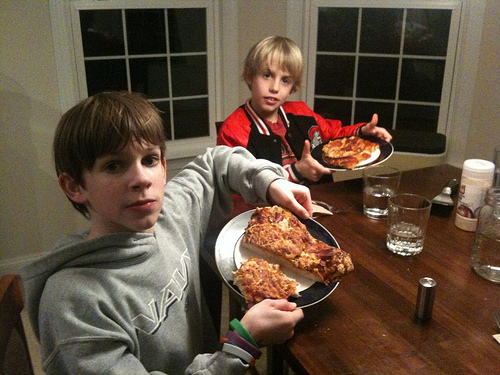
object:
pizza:
[321, 135, 381, 170]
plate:
[310, 135, 394, 171]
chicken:
[232, 257, 303, 304]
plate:
[214, 205, 342, 310]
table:
[199, 164, 496, 375]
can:
[455, 158, 496, 232]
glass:
[385, 193, 432, 257]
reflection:
[214, 220, 249, 271]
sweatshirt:
[19, 144, 289, 375]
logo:
[131, 246, 192, 336]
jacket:
[217, 98, 368, 198]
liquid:
[386, 223, 425, 256]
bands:
[221, 317, 263, 365]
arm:
[43, 278, 255, 375]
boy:
[216, 34, 392, 198]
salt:
[414, 276, 437, 322]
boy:
[18, 91, 313, 375]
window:
[312, 3, 456, 134]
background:
[0, 0, 499, 266]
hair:
[239, 35, 304, 94]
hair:
[52, 92, 167, 220]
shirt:
[260, 114, 299, 167]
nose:
[128, 156, 153, 191]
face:
[82, 131, 165, 230]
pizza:
[231, 205, 355, 304]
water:
[472, 231, 500, 281]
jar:
[469, 188, 500, 282]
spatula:
[430, 178, 460, 218]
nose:
[269, 74, 281, 94]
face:
[251, 55, 295, 112]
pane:
[166, 7, 210, 54]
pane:
[122, 5, 169, 56]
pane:
[77, 5, 125, 57]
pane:
[84, 57, 128, 98]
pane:
[169, 54, 210, 98]